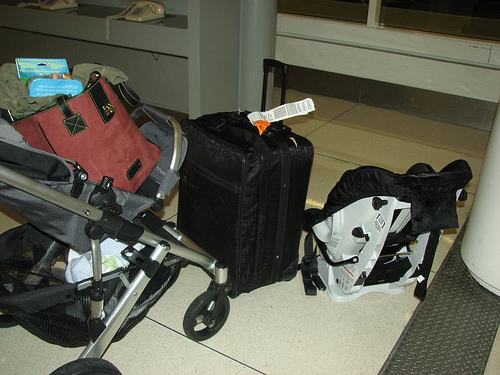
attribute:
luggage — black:
[173, 107, 317, 303]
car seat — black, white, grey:
[299, 157, 473, 310]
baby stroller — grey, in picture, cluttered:
[0, 57, 232, 373]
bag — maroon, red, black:
[9, 71, 163, 197]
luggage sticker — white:
[246, 96, 317, 128]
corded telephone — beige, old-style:
[104, 1, 168, 42]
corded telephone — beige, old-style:
[13, 0, 83, 13]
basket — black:
[0, 223, 182, 349]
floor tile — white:
[265, 78, 361, 125]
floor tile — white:
[325, 102, 492, 160]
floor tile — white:
[303, 119, 485, 196]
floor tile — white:
[305, 149, 364, 209]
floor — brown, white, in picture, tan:
[0, 83, 492, 374]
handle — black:
[261, 56, 292, 133]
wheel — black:
[182, 288, 230, 345]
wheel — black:
[42, 356, 130, 374]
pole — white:
[235, 0, 280, 114]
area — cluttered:
[1, 56, 475, 374]